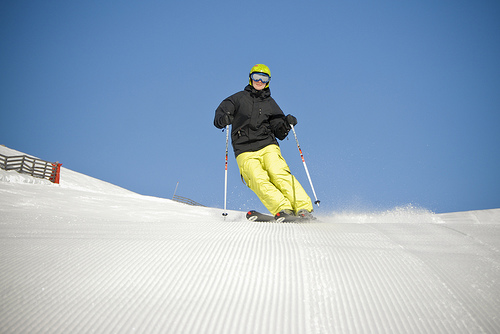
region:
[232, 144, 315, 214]
bright yellow ski pants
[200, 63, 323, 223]
person downhill skiing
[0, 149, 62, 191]
section of brown fence with bright red section on end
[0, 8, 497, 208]
bright blue sky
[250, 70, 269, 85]
gray and blue ski goggles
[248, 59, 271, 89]
yellow ski helmet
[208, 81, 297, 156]
black ski jacket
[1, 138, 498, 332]
well-groomed ski slope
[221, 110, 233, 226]
white ski pole with red and black accents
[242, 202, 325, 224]
downhill skis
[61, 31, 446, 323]
PIcture taken outdoors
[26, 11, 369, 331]
Picture taken during the day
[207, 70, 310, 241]
A man is skiing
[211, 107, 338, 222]
The man has two poles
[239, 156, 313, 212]
The man has yellow pants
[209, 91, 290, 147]
The man wears a black jacket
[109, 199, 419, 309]
The snow has been groomed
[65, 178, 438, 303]
Snow covers the mountain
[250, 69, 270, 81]
The man wears goggles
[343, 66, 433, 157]
The sky is void of clouds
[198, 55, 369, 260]
person skiing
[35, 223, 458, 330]
thin lines in the snow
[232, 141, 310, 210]
bright yellow snow pants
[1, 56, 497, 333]
person skiing down a slope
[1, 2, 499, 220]
bright blue sky with no clouds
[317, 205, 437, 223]
snow being kicked up from the skis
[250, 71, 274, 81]
ski goggles on the face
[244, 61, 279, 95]
yellow helmet with a black strap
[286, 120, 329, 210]
silver and red ski pole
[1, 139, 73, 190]
small fence in the snow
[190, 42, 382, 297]
a man skiing down a snow slope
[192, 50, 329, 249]
a man wearing a ski suit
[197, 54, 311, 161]
a man wearing a black jacket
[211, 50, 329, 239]
a man wearing yellow ski pants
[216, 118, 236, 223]
a red, black, and white ski pole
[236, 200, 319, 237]
a pair of snow skies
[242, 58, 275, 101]
a man wearing a yellow ski helmet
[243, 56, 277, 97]
a man wearing ski goggles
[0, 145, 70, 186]
a gray and red snow fence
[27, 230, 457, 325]
a thick coat of snow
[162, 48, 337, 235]
A person is snowboarding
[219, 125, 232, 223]
A person holding skipole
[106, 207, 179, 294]
White color snow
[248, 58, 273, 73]
A person wearing helmet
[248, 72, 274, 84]
A person wearing goggles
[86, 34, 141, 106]
A blu color sky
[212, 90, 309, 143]
A man wearing black color jacket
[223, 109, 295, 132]
A man wearing black color gloves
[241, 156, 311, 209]
A man wearing yellow color trouser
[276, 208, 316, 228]
Pair of shoes